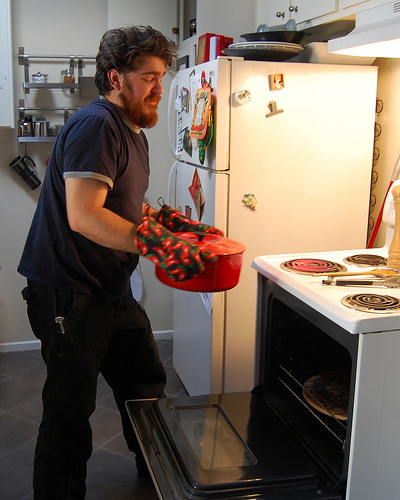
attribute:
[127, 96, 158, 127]
beard — brown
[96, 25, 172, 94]
hair — dark colored, curly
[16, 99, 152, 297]
shirt — dark colored, black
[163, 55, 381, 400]
refrigerator — large, white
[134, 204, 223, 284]
gloves — red, green, black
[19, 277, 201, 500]
pants — black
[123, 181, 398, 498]
stove — white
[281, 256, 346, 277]
burner — red, hot, red hot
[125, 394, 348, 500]
oven door — black, open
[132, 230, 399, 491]
oven — open, wide open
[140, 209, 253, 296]
pot — red, hot, large